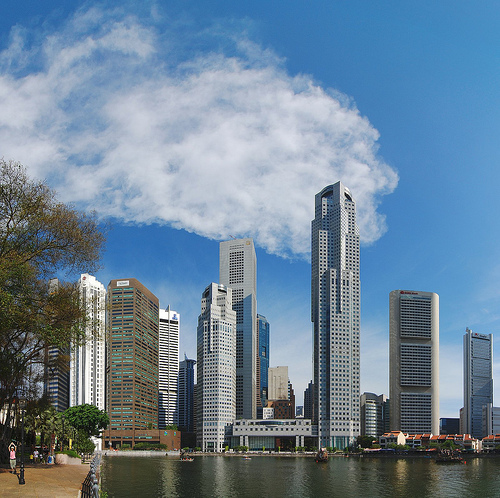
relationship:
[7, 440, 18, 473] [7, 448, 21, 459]
people wearing shirt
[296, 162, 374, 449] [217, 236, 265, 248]
building with roof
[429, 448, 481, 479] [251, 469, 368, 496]
boat on water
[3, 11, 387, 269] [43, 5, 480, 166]
clouds in sky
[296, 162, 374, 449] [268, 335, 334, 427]
building in distance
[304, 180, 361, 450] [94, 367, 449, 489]
building along harbor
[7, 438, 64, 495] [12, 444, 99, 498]
people on walkway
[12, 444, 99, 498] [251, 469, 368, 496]
walkway on water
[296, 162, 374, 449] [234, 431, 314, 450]
building on supports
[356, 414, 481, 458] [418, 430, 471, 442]
buildings with roofs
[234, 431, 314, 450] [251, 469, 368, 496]
pilings on water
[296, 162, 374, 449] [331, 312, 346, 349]
building with windows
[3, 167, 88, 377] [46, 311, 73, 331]
tree losing leaves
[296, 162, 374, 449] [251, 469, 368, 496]
building near water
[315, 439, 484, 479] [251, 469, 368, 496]
boats on water